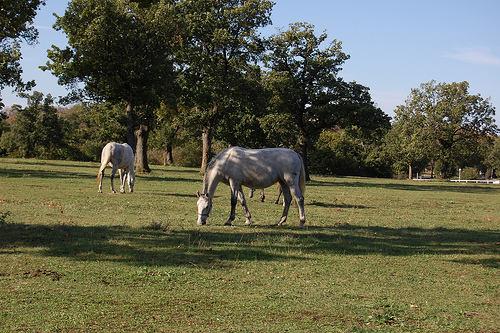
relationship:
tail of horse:
[294, 150, 305, 199] [194, 146, 308, 225]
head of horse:
[194, 190, 213, 225] [194, 146, 308, 225]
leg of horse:
[227, 181, 237, 225] [194, 146, 308, 225]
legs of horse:
[234, 185, 251, 218] [194, 146, 308, 225]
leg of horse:
[276, 180, 291, 219] [194, 146, 308, 225]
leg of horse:
[282, 174, 306, 218] [194, 146, 308, 225]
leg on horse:
[282, 174, 306, 218] [194, 146, 308, 225]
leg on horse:
[276, 180, 291, 223] [194, 146, 308, 225]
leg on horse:
[227, 179, 239, 221] [194, 146, 308, 225]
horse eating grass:
[194, 146, 308, 225] [4, 175, 496, 331]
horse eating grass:
[194, 146, 308, 225] [2, 156, 499, 331]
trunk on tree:
[128, 106, 155, 172] [38, 2, 278, 174]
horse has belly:
[194, 146, 308, 225] [240, 173, 278, 191]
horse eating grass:
[98, 142, 137, 194] [2, 156, 499, 331]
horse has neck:
[194, 146, 308, 225] [199, 167, 219, 196]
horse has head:
[194, 146, 308, 225] [192, 189, 212, 223]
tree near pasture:
[366, 81, 499, 180] [0, 155, 499, 332]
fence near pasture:
[407, 164, 499, 188] [0, 155, 499, 332]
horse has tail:
[194, 146, 308, 225] [296, 154, 313, 192]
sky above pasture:
[1, 0, 500, 139] [0, 155, 499, 332]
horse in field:
[98, 142, 137, 194] [2, 155, 499, 332]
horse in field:
[194, 146, 308, 225] [2, 155, 499, 332]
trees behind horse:
[97, 33, 299, 133] [91, 121, 143, 201]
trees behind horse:
[97, 33, 299, 133] [190, 135, 330, 224]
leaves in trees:
[21, 110, 122, 136] [22, 104, 315, 141]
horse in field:
[98, 142, 137, 194] [40, 163, 451, 322]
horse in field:
[194, 146, 308, 225] [40, 163, 451, 322]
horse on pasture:
[98, 142, 137, 194] [0, 155, 499, 332]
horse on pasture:
[194, 146, 308, 225] [0, 155, 499, 332]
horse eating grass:
[98, 142, 137, 194] [103, 225, 321, 293]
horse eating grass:
[194, 146, 308, 225] [103, 225, 321, 293]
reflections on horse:
[230, 151, 268, 172] [187, 136, 323, 235]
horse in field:
[193, 138, 313, 234] [23, 182, 128, 311]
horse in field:
[194, 146, 308, 225] [39, 143, 446, 308]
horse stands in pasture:
[98, 142, 137, 194] [0, 155, 499, 332]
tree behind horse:
[366, 81, 499, 180] [195, 135, 315, 230]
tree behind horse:
[161, 5, 258, 179] [190, 144, 313, 242]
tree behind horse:
[366, 81, 499, 180] [186, 129, 319, 226]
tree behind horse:
[366, 81, 499, 180] [153, 133, 321, 225]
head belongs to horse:
[190, 186, 220, 228] [194, 146, 308, 225]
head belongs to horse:
[126, 170, 137, 189] [91, 139, 151, 197]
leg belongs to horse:
[227, 179, 239, 221] [194, 146, 308, 225]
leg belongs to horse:
[287, 174, 310, 234] [176, 144, 316, 228]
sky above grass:
[1, 0, 495, 139] [2, 156, 499, 331]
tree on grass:
[366, 81, 499, 180] [2, 156, 499, 331]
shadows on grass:
[3, 158, 498, 291] [2, 156, 499, 331]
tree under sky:
[366, 81, 499, 180] [1, 0, 495, 139]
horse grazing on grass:
[194, 146, 308, 225] [2, 156, 499, 331]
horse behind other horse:
[98, 142, 137, 194] [180, 139, 320, 229]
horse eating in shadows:
[194, 146, 308, 225] [0, 221, 500, 268]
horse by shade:
[194, 146, 308, 225] [1, 204, 498, 280]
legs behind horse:
[242, 174, 272, 212] [187, 136, 323, 235]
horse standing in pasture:
[194, 146, 308, 225] [0, 155, 499, 332]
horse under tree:
[98, 142, 137, 194] [50, 0, 277, 199]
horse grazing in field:
[194, 146, 308, 225] [2, 155, 499, 332]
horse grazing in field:
[85, 130, 156, 195] [2, 155, 499, 332]